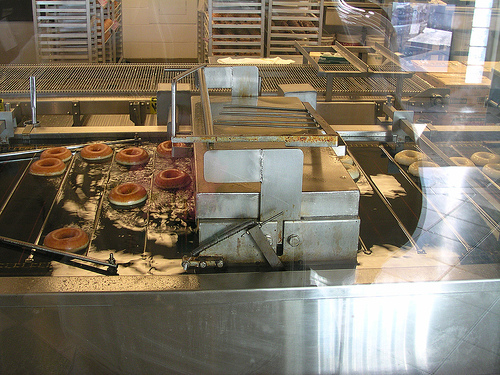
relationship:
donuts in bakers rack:
[214, 27, 260, 35] [198, 1, 265, 62]